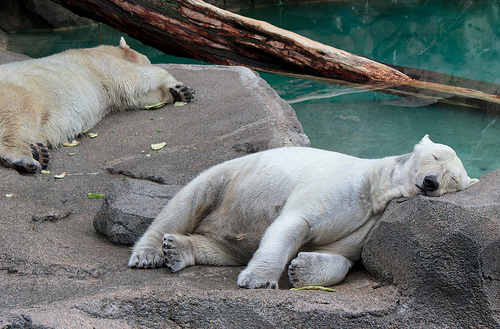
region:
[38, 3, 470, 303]
two bears laying down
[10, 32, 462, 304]
two bears on ground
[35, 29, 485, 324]
two bears on rocks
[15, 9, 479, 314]
two polar bears laying down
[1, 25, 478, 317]
two polar bears laying on rocks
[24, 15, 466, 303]
two polar bears sleeping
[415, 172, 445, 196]
black nose of polar bear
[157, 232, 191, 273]
black and white paw of bear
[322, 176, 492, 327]
grey rock by bear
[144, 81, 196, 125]
black paws of bear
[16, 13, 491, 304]
The bears are taking a nap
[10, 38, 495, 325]
The bears are sleeping very soundly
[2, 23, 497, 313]
Some bears are inside a zoo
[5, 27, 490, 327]
Some bears are taking it very easy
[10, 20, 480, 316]
Some bears are laying on some rocks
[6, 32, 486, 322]
The bears are big polar bears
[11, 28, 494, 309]
The bears are male and female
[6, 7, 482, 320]
The bears are waiting to be fed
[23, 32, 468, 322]
The bears are close to the water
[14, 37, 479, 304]
The bears are enjoying the day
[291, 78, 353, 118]
ripples on the water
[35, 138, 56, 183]
toe's of the bear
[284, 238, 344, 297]
paw of the bear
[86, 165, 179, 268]
rock on the ground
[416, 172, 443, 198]
nose on the bear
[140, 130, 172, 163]
rind on the ground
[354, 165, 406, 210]
wrinkles of the skin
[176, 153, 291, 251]
tufts of fur on the bear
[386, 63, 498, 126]
log under the water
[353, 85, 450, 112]
reflection on the water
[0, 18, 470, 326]
two bears on rocks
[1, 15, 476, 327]
two polar bears laying down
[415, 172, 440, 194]
black nose of polar bear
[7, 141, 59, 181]
black feet of polar bear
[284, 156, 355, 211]
white fur of polar bear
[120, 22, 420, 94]
brown wooden log in water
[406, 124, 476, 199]
head of a polar bear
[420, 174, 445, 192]
nose of a polar bear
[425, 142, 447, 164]
eye of a polar bear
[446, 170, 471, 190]
eye of a polar bear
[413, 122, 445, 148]
ear of a polar bear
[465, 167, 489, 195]
ear of a polar bear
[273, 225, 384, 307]
paw of a polar bear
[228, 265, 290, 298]
paw of a polar bear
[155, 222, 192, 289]
paw of a polar bear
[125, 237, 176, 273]
paw of a polar bear